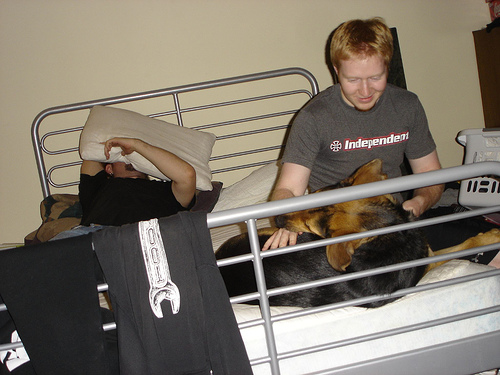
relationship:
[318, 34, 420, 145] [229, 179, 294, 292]
man on bed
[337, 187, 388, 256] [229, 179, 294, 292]
dog on bed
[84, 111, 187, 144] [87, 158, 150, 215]
pillow on guy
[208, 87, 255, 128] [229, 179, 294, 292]
headboard on bed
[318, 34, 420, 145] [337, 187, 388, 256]
man petting dog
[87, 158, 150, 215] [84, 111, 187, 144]
guy with pillow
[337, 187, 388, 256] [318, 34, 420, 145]
dog licking man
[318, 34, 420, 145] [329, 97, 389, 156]
man wearing shirt